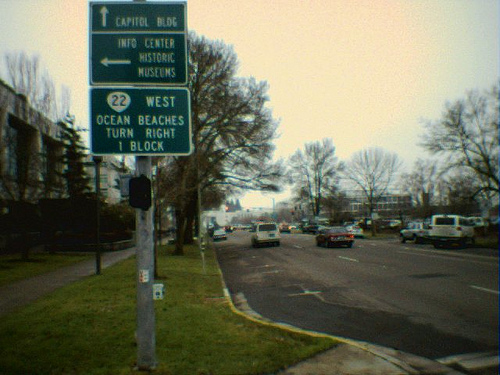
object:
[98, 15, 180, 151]
writing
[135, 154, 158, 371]
pole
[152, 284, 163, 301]
attachment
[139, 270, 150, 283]
attachment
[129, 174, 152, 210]
attachment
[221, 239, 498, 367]
pavement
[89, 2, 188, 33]
sign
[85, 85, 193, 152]
signs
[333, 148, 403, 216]
trees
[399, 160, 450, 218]
trees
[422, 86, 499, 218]
trees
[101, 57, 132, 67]
white arrow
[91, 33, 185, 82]
green background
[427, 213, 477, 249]
van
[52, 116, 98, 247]
tree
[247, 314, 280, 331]
curb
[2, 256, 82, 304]
sidewalk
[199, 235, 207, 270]
parking meter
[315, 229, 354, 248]
car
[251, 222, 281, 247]
car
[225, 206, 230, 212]
light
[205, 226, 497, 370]
street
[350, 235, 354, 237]
light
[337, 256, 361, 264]
street lines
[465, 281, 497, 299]
street lines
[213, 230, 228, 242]
cars